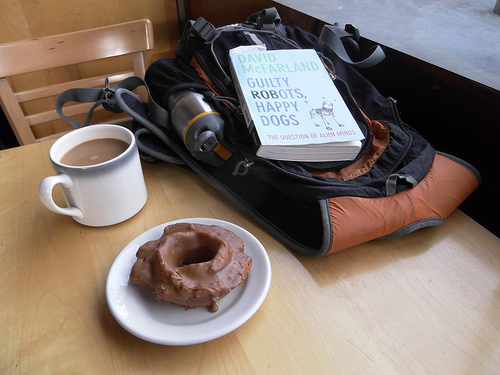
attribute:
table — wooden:
[6, 157, 489, 354]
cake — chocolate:
[133, 178, 251, 314]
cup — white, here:
[20, 132, 191, 223]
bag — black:
[129, 18, 465, 247]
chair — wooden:
[5, 28, 175, 117]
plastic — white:
[165, 87, 226, 135]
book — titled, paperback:
[225, 38, 361, 153]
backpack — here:
[50, 33, 496, 356]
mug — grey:
[55, 148, 173, 233]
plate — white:
[77, 201, 289, 340]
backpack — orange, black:
[124, 25, 494, 276]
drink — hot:
[58, 139, 126, 170]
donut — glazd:
[102, 219, 269, 315]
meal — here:
[14, 100, 243, 356]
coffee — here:
[21, 126, 173, 172]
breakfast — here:
[17, 74, 322, 342]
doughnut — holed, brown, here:
[117, 214, 270, 322]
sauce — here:
[70, 141, 113, 172]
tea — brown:
[58, 122, 121, 159]